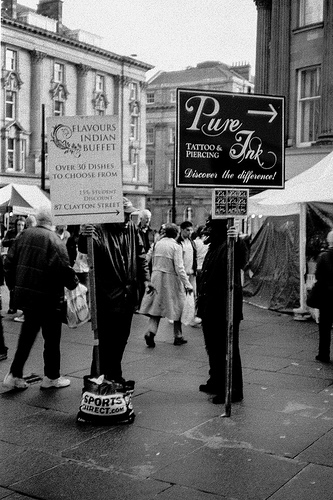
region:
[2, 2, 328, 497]
Black and white filter.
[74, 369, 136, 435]
Plastic bag is full.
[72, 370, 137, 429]
The bag says sports direct.com.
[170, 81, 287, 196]
Black sign with white text.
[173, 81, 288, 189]
Sign is for tattoos and piercing.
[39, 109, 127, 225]
Sign is white with black text.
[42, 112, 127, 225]
Sign is for a indian buffet.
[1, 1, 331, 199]
Buildings in the background.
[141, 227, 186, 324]
Person in white coat.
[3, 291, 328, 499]
Concrete tiles on ground.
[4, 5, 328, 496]
The photo is black and white.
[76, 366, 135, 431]
The bag is plastic.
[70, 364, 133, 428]
The bag is full.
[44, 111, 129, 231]
The sign is white.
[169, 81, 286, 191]
The sign is black.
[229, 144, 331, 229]
The tent is white.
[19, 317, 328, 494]
The tiles are square.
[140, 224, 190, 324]
The woman's coat is white.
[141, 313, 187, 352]
The woman's shoes are black.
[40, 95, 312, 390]
black and white photo people on busy street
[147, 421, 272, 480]
large cement stones on ground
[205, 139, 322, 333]
street fair where vendors have goods for sale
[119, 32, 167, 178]
large buildings in the background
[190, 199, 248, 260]
man holding sign with gorilla mask on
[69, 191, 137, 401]
man holding sign with baseball cap on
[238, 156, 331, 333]
white canopy for vendors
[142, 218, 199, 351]
woman holding bag and walking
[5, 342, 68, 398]
man with white tennis shoes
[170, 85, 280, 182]
sign advertising tattoos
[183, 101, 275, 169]
sign for a tattoo parlor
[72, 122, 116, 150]
sign for Flavours Indian Buffet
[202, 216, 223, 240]
gorilla mask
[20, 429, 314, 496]
stone pavement squares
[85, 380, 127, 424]
plastic shopping bag sitting on the ground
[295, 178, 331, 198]
white tent roof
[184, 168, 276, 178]
sign that says Imagine the Difference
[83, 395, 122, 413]
logo for SportsDirect.com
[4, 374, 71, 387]
man's white shoes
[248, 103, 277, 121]
white arrow on a black sign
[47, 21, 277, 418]
a black and white scene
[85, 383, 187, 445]
a advertisement for sports direct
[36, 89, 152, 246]
flavors indian buffet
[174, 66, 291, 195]
the ad for tattos and piercing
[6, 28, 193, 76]
the top of a building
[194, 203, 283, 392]
a man dressed as a gorilla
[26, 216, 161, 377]
the man holding the indian sign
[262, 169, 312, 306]
the tent canopy on the side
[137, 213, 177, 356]
the lady walking away from the scene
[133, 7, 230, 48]
the sky in the photo